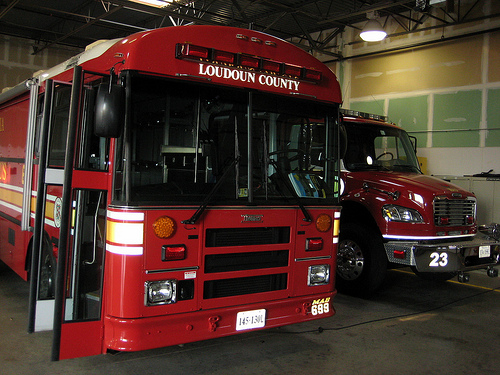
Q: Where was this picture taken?
A: In a garage.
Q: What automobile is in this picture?
A: Two trucks.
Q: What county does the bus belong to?
A: London county.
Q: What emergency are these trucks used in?
A: Fires.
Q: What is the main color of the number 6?
A: White.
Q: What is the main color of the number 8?
A: White.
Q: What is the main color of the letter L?
A: White.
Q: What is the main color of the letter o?
A: White.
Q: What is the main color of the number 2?
A: White.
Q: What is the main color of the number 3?
A: White.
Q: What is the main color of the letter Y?
A: White.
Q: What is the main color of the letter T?
A: White.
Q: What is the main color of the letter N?
A: White.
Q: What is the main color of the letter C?
A: White.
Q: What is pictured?
A: Bus.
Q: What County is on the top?
A: Loudoun.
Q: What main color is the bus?
A: Red.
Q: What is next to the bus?
A: Truck.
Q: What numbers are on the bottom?
A: 699.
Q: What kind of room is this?
A: Garage.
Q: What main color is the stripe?
A: Yellow.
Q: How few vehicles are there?
A: 2.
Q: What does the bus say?
A: Loudoun county.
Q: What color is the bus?
A: Red.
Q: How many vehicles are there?
A: Two.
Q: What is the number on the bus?
A: 699.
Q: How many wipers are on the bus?
A: Two.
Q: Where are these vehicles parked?
A: In a garage.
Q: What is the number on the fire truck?
A: 23.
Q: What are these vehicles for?
A: To fight fires.